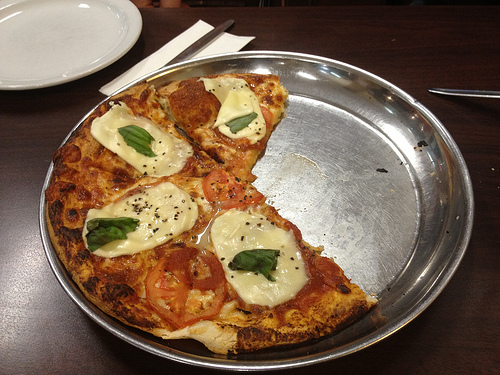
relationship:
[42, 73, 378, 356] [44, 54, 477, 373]
pizza on top of pan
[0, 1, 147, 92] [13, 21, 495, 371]
plate on top of table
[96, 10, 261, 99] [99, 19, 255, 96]
napkin made of napkin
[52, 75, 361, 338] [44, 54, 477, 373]
pizza on pan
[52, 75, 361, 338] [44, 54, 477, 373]
pizza in pan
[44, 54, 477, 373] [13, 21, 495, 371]
pan on table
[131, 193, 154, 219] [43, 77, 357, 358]
seasoning on pizza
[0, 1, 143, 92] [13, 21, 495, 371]
plate sitting on table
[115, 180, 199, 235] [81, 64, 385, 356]
cheese on pizza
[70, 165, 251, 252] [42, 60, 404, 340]
toppings on pizza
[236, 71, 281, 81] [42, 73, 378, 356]
crust on pizza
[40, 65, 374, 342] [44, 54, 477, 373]
sliced pizza on pan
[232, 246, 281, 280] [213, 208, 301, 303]
herb on cheese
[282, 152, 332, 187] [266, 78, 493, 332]
grease on pan